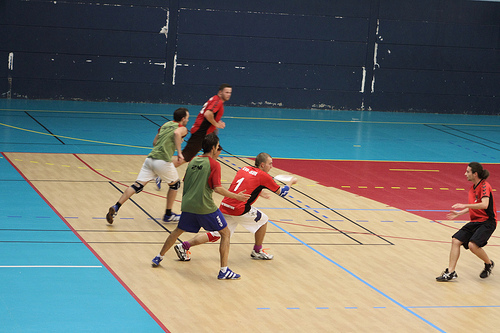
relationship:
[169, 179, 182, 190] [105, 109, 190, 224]
pad on man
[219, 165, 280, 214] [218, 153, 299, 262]
jersey on man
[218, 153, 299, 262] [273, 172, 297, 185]
man playing with frisbee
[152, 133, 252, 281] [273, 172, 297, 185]
man playing with frisbee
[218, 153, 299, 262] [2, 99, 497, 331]
man running on floor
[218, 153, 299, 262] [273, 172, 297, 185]
man throwing frisbee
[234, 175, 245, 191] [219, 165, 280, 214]
number on jersey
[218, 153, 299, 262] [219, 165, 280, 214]
man wearing a jersey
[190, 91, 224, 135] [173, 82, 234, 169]
jersey worn by man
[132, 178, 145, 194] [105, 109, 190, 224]
pad on man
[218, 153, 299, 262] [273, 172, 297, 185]
man playing frisbee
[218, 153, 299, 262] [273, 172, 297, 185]
man holding frisbee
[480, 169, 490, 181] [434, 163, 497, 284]
ponytail on man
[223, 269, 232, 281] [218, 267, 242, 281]
stripe on shoe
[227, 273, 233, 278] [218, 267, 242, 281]
stripe on shoe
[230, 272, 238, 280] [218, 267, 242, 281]
stripe on shoe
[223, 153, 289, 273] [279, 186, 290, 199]
man wearing pad